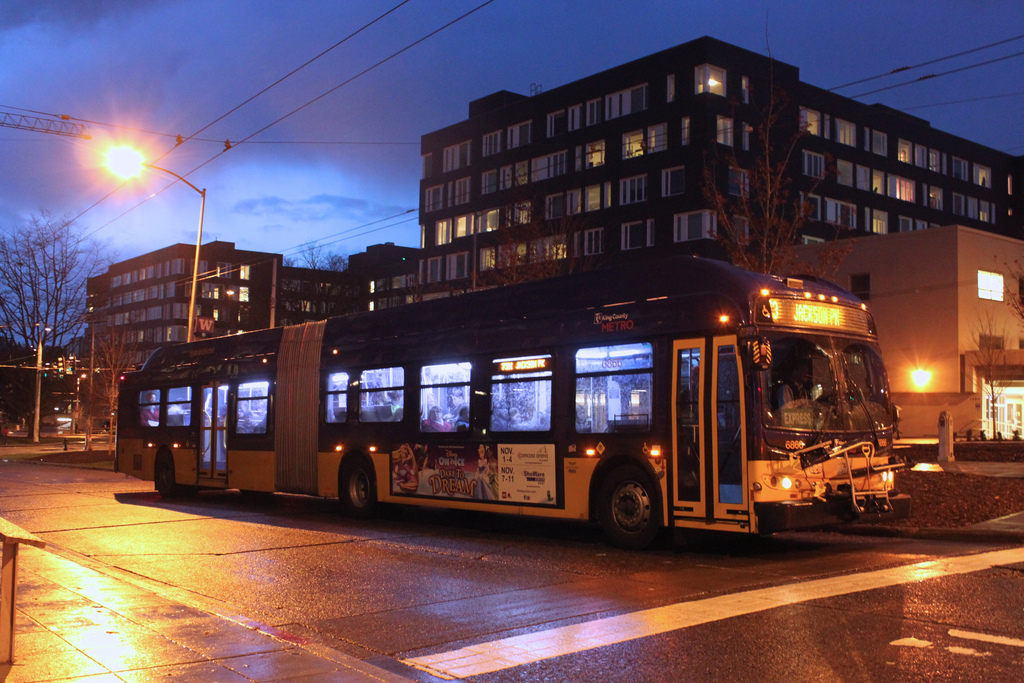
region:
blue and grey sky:
[235, 84, 344, 208]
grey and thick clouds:
[298, 28, 439, 193]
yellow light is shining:
[82, 116, 134, 215]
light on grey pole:
[89, 128, 198, 332]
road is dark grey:
[61, 485, 290, 584]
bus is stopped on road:
[123, 372, 869, 569]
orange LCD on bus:
[730, 280, 854, 342]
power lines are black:
[196, 28, 405, 156]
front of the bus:
[663, 243, 943, 556]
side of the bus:
[35, 243, 783, 545]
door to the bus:
[582, 300, 795, 519]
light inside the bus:
[97, 323, 712, 478]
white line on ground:
[540, 516, 772, 678]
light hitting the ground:
[78, 471, 326, 659]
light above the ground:
[62, 121, 200, 220]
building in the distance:
[335, 38, 826, 283]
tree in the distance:
[2, 180, 142, 376]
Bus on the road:
[109, 241, 907, 551]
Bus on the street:
[105, 238, 912, 552]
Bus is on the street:
[90, 231, 919, 557]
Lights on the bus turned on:
[136, 332, 722, 470]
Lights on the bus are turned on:
[130, 332, 682, 475]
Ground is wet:
[4, 403, 1020, 679]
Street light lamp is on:
[84, 119, 221, 363]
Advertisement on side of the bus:
[371, 422, 578, 511]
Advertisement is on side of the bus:
[365, 425, 563, 509]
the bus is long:
[91, 249, 935, 562]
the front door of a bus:
[650, 322, 765, 531]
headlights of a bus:
[761, 453, 908, 502]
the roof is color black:
[130, 230, 865, 387]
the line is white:
[375, 536, 1023, 680]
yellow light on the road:
[15, 480, 213, 680]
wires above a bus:
[0, 3, 612, 367]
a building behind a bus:
[357, 25, 1022, 474]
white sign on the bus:
[479, 429, 579, 521]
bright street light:
[68, 107, 174, 212]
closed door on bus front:
[656, 320, 754, 542]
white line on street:
[387, 531, 1021, 672]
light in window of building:
[688, 53, 746, 117]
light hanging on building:
[893, 335, 958, 405]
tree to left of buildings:
[9, 209, 104, 356]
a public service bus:
[113, 254, 910, 561]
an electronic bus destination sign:
[768, 291, 874, 334]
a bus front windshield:
[759, 332, 897, 431]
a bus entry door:
[673, 332, 751, 520]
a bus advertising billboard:
[386, 434, 563, 510]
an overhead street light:
[81, 131, 203, 198]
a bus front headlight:
[780, 472, 793, 489]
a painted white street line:
[401, 539, 1022, 676]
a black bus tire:
[593, 460, 664, 549]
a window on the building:
[637, 110, 648, 115]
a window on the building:
[631, 162, 666, 229]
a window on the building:
[535, 189, 584, 224]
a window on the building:
[520, 186, 543, 241]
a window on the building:
[845, 139, 868, 191]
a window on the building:
[874, 177, 900, 197]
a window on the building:
[204, 247, 239, 287]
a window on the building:
[476, 224, 508, 247]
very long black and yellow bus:
[108, 250, 912, 541]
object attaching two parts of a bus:
[263, 304, 331, 497]